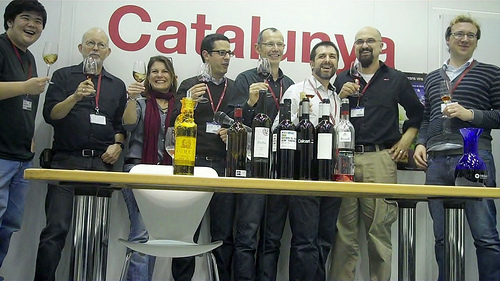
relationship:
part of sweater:
[133, 91, 185, 175] [119, 89, 190, 180]